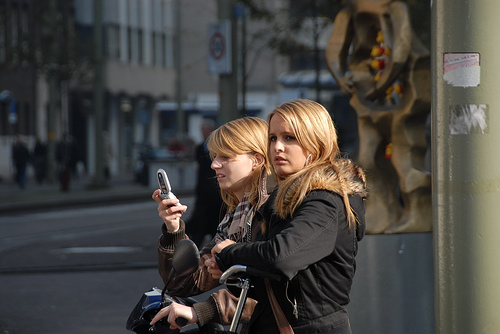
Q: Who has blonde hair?
A: Two women.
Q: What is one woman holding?
A: Cell phone.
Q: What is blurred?
A: People in the background.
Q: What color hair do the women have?
A: Blonde.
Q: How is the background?
A: Blurry.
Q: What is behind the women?
A: Sculpture.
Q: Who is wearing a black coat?
A: THe woman in front.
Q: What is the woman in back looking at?
A: Cell phone.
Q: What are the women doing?
A: Waiting.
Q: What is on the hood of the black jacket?
A: Fur.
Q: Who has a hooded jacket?
A: The first woman.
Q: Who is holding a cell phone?
A: The woman in back.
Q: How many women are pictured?
A: Two.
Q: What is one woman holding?
A: Cell phone.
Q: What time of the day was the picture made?
A: Daytime.